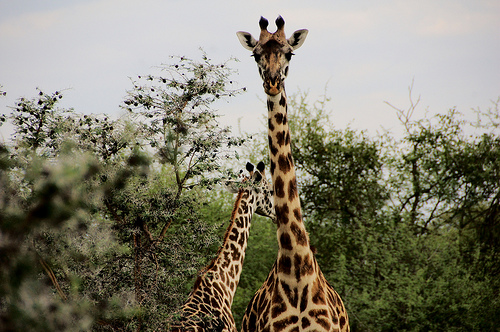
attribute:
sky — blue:
[362, 49, 427, 79]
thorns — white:
[101, 224, 206, 329]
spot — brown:
[273, 202, 296, 219]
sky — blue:
[10, 2, 497, 223]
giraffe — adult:
[234, 13, 353, 330]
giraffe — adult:
[157, 160, 282, 328]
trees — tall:
[2, 44, 497, 320]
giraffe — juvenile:
[161, 148, 296, 329]